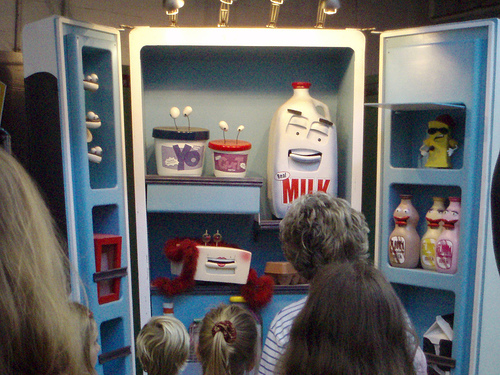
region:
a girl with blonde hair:
[195, 303, 262, 373]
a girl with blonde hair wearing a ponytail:
[195, 302, 262, 374]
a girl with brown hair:
[271, 260, 420, 374]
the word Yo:
[170, 142, 202, 170]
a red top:
[289, 80, 311, 90]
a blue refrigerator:
[19, 13, 498, 373]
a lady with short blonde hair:
[279, 190, 370, 282]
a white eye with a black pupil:
[285, 114, 309, 141]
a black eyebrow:
[286, 105, 302, 118]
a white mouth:
[285, 147, 323, 173]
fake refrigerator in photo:
[22, 25, 406, 367]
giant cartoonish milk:
[265, 77, 330, 227]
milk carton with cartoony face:
[260, 70, 347, 228]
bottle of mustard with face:
[414, 110, 466, 180]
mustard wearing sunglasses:
[417, 115, 459, 150]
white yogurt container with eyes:
[151, 90, 211, 187]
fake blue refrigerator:
[32, 12, 497, 356]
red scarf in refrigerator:
[160, 224, 284, 328]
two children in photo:
[111, 264, 319, 374]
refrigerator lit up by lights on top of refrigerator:
[91, 2, 433, 190]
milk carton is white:
[267, 79, 355, 216]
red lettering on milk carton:
[281, 171, 338, 207]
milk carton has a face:
[268, 99, 358, 170]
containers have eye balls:
[156, 96, 255, 177]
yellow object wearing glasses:
[420, 108, 457, 176]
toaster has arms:
[167, 231, 289, 317]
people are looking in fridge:
[0, 44, 488, 369]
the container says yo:
[166, 141, 218, 181]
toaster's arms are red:
[149, 230, 296, 304]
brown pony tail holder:
[202, 311, 253, 349]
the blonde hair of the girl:
[196, 295, 266, 373]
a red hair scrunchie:
[207, 315, 239, 347]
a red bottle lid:
[286, 77, 314, 94]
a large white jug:
[263, 75, 343, 219]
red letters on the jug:
[278, 172, 338, 207]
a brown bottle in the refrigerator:
[383, 188, 422, 267]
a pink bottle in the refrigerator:
[432, 192, 463, 274]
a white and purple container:
[205, 132, 257, 182]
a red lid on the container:
[205, 137, 255, 154]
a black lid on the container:
[150, 123, 216, 143]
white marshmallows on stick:
[155, 100, 204, 122]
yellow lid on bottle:
[222, 292, 252, 305]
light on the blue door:
[337, 28, 423, 83]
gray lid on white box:
[199, 246, 239, 266]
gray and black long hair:
[17, 185, 79, 331]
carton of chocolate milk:
[385, 185, 421, 273]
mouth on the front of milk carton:
[279, 146, 340, 168]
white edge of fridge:
[186, 25, 236, 50]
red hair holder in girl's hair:
[200, 317, 242, 345]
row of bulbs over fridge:
[156, 2, 358, 20]